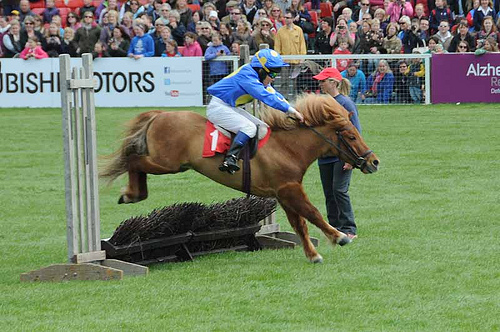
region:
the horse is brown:
[142, 111, 409, 234]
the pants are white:
[205, 97, 255, 134]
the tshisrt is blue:
[210, 70, 296, 124]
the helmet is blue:
[256, 48, 295, 75]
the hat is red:
[313, 68, 345, 86]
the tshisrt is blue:
[338, 95, 371, 170]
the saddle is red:
[200, 123, 225, 160]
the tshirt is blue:
[360, 70, 402, 98]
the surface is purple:
[431, 53, 495, 100]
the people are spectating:
[13, 25, 478, 50]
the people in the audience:
[0, 0, 498, 105]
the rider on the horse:
[204, 47, 305, 174]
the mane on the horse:
[255, 90, 350, 130]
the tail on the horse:
[97, 111, 160, 188]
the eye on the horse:
[347, 134, 356, 141]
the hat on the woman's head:
[312, 69, 344, 83]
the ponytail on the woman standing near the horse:
[339, 75, 350, 95]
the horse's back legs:
[117, 172, 147, 204]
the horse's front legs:
[275, 182, 349, 265]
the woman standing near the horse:
[312, 68, 361, 240]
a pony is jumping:
[108, 79, 390, 271]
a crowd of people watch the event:
[13, 1, 497, 93]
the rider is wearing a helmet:
[236, 45, 290, 72]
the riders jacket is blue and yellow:
[207, 65, 295, 117]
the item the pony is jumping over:
[105, 191, 287, 281]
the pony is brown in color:
[100, 100, 369, 255]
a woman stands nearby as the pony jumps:
[313, 58, 364, 249]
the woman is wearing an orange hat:
[309, 65, 342, 85]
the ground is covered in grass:
[9, 96, 494, 329]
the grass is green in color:
[215, 268, 480, 324]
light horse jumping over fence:
[115, 87, 375, 267]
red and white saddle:
[203, 115, 273, 157]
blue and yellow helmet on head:
[249, 44, 282, 75]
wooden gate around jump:
[19, 47, 152, 279]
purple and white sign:
[429, 50, 499, 102]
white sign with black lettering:
[1, 56, 206, 113]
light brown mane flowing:
[259, 87, 353, 132]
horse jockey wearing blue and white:
[198, 37, 305, 177]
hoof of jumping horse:
[336, 228, 356, 248]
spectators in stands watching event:
[0, 2, 498, 47]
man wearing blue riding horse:
[90, 42, 381, 264]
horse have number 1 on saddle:
[90, 90, 382, 266]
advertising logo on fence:
[0, 50, 498, 106]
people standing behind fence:
[0, 0, 498, 105]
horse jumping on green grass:
[1, 102, 498, 328]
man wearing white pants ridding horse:
[90, 42, 382, 268]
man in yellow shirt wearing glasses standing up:
[270, 4, 306, 101]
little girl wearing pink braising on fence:
[0, 31, 497, 105]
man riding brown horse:
[82, 45, 380, 269]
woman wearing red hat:
[305, 65, 364, 245]